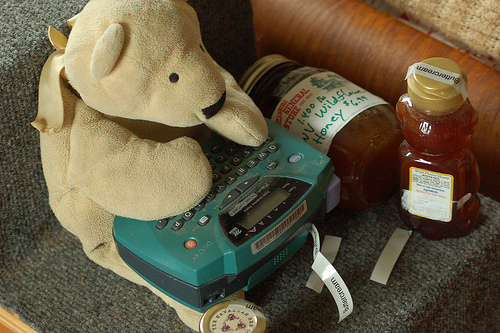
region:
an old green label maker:
[115, 116, 330, 306]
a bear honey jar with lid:
[395, 55, 485, 245]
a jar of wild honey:
[235, 55, 390, 205]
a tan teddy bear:
[30, 1, 275, 326]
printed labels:
[309, 226, 419, 329]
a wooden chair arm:
[251, 3, 498, 203]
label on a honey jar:
[407, 166, 454, 224]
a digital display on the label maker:
[235, 184, 295, 234]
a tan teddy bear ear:
[90, 20, 131, 82]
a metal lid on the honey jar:
[241, 47, 289, 91]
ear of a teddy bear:
[86, 13, 141, 77]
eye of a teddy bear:
[149, 73, 190, 87]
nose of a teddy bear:
[195, 88, 237, 135]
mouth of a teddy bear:
[140, 103, 218, 134]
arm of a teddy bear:
[85, 132, 227, 229]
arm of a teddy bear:
[215, 91, 263, 135]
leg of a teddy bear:
[135, 239, 216, 306]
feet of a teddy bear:
[192, 305, 282, 332]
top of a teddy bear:
[136, 6, 211, 60]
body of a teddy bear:
[25, 21, 262, 235]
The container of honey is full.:
[394, 54, 480, 244]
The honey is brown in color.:
[393, 50, 478, 247]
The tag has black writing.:
[308, 256, 358, 323]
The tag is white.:
[370, 226, 415, 298]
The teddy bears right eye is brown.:
[161, 68, 181, 81]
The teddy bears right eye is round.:
[163, 66, 179, 82]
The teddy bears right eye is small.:
[165, 67, 184, 84]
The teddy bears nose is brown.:
[201, 87, 233, 118]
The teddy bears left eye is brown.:
[195, 37, 207, 52]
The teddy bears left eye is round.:
[195, 38, 207, 50]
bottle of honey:
[397, 62, 477, 232]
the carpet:
[52, 267, 91, 307]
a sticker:
[318, 263, 358, 326]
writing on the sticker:
[323, 274, 342, 292]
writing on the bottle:
[299, 99, 357, 129]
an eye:
[161, 71, 186, 85]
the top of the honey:
[414, 80, 441, 103]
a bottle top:
[206, 309, 256, 330]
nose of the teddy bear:
[200, 101, 229, 118]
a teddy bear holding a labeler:
[50, 0, 304, 330]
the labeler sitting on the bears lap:
[125, 120, 339, 302]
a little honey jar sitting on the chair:
[393, 58, 480, 235]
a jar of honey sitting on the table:
[233, 44, 403, 202]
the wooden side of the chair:
[255, 0, 497, 202]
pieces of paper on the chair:
[311, 227, 413, 317]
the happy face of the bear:
[146, 24, 229, 134]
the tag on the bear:
[196, 301, 275, 331]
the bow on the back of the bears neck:
[32, 13, 77, 135]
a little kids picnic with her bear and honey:
[32, 38, 487, 317]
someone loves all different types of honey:
[291, 44, 461, 289]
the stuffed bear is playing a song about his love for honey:
[32, 45, 467, 317]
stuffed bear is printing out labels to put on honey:
[20, 38, 481, 278]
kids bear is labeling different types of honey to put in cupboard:
[51, 39, 477, 312]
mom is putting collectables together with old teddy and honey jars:
[53, 49, 482, 318]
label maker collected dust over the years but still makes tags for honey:
[74, 38, 484, 295]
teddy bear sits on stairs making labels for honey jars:
[70, 39, 458, 305]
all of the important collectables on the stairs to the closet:
[67, 47, 486, 314]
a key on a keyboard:
[267, 136, 277, 148]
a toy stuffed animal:
[40, 5, 270, 321]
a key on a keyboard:
[251, 150, 262, 160]